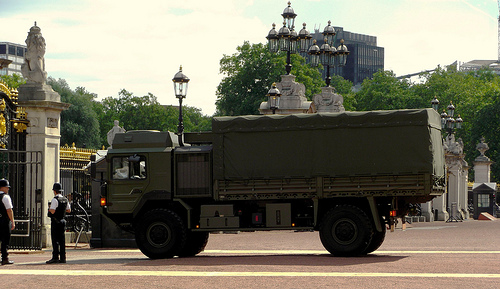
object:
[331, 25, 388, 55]
top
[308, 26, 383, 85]
building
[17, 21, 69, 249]
fence pillar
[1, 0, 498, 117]
sky